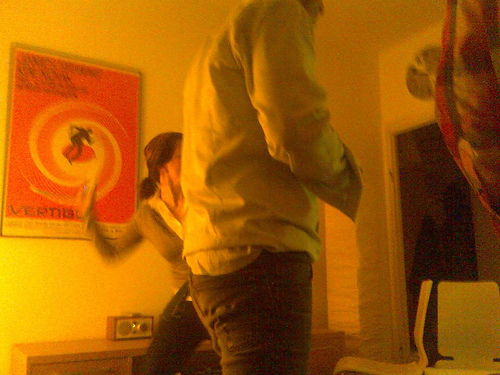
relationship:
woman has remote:
[80, 131, 210, 374] [80, 155, 104, 209]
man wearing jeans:
[179, 1, 362, 373] [187, 249, 313, 374]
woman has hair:
[80, 131, 210, 374] [135, 131, 182, 198]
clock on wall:
[405, 47, 440, 100] [0, 0, 496, 374]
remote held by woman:
[80, 155, 104, 209] [80, 131, 210, 374]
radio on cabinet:
[106, 314, 153, 339] [12, 330, 346, 372]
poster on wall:
[2, 44, 142, 241] [0, 0, 496, 374]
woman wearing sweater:
[80, 131, 210, 374] [83, 199, 193, 287]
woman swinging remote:
[80, 131, 210, 374] [80, 155, 104, 209]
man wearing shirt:
[179, 1, 362, 373] [183, 0, 363, 278]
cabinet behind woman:
[12, 330, 346, 372] [80, 131, 210, 374]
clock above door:
[405, 47, 440, 100] [395, 121, 476, 364]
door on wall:
[395, 121, 476, 364] [0, 0, 496, 374]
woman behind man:
[80, 131, 210, 374] [179, 1, 362, 373]